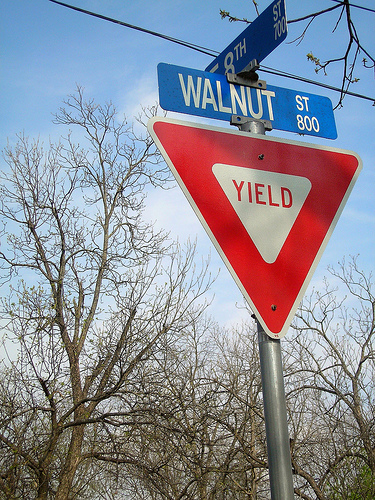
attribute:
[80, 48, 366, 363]
sign — street, red, yield, walnut, 58th, triangular, blue, three, behind, over, white, silver, triangle, above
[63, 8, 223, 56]
wire — black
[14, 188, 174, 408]
tree — branch, bare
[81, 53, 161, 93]
sky — blue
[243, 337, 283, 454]
pole — silver, gray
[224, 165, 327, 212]
word — yeild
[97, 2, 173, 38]
line — electric